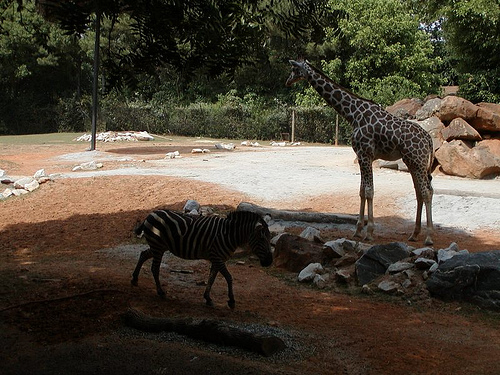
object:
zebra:
[129, 209, 273, 309]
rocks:
[375, 280, 400, 293]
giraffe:
[285, 56, 435, 244]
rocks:
[412, 235, 500, 308]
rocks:
[372, 95, 500, 181]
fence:
[2, 94, 353, 146]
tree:
[31, 0, 353, 153]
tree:
[326, 0, 500, 103]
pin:
[292, 110, 295, 142]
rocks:
[353, 241, 415, 294]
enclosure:
[0, 64, 499, 373]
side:
[317, 84, 430, 237]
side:
[140, 215, 252, 305]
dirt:
[7, 192, 100, 371]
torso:
[132, 215, 235, 307]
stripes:
[152, 215, 229, 260]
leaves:
[360, 5, 420, 32]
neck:
[216, 218, 245, 247]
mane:
[227, 209, 269, 227]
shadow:
[0, 195, 485, 375]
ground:
[16, 121, 466, 372]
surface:
[52, 263, 483, 373]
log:
[127, 306, 287, 356]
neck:
[310, 77, 359, 120]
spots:
[310, 80, 317, 87]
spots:
[313, 72, 320, 79]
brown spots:
[383, 128, 398, 148]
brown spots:
[336, 94, 363, 115]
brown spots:
[410, 143, 424, 158]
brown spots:
[355, 109, 374, 128]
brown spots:
[416, 167, 425, 192]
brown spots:
[356, 140, 375, 159]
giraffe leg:
[362, 157, 374, 223]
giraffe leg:
[418, 172, 432, 235]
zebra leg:
[222, 267, 235, 299]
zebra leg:
[134, 250, 150, 280]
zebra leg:
[206, 261, 218, 294]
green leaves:
[3, 1, 62, 73]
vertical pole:
[90, 3, 101, 148]